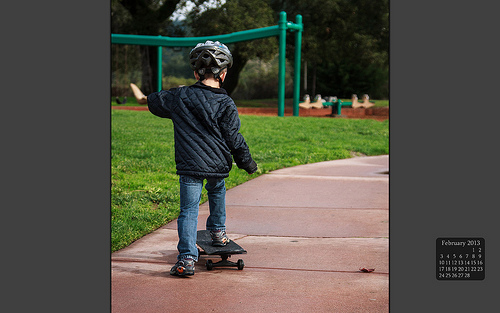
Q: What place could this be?
A: It is a park.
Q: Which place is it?
A: It is a park.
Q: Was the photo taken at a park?
A: Yes, it was taken in a park.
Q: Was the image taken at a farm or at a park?
A: It was taken at a park.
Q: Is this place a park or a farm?
A: It is a park.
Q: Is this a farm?
A: No, it is a park.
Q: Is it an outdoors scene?
A: Yes, it is outdoors.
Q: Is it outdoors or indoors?
A: It is outdoors.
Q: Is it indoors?
A: No, it is outdoors.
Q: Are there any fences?
A: No, there are no fences.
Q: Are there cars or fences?
A: No, there are no fences or cars.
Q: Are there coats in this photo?
A: Yes, there is a coat.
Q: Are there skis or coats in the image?
A: Yes, there is a coat.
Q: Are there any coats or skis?
A: Yes, there is a coat.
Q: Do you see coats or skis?
A: Yes, there is a coat.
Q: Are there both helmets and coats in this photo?
A: Yes, there are both a coat and a helmet.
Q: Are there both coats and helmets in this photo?
A: Yes, there are both a coat and a helmet.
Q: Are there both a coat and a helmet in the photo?
A: Yes, there are both a coat and a helmet.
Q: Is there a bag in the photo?
A: No, there are no bags.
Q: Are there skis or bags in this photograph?
A: No, there are no bags or skis.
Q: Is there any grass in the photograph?
A: Yes, there is grass.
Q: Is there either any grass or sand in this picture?
A: Yes, there is grass.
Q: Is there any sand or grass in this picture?
A: Yes, there is grass.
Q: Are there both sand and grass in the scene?
A: No, there is grass but no sand.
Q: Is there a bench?
A: No, there are no benches.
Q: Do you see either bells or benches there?
A: No, there are no benches or bells.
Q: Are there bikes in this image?
A: No, there are no bikes.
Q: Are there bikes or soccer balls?
A: No, there are no bikes or soccer balls.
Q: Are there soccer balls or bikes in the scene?
A: No, there are no bikes or soccer balls.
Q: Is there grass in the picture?
A: Yes, there is grass.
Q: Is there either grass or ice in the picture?
A: Yes, there is grass.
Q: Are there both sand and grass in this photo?
A: No, there is grass but no sand.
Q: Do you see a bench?
A: No, there are no benches.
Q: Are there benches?
A: No, there are no benches.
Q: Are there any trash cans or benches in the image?
A: No, there are no benches or trash cans.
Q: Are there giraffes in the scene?
A: No, there are no giraffes.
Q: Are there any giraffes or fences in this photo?
A: No, there are no giraffes or fences.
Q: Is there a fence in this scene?
A: No, there are no fences.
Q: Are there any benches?
A: No, there are no benches.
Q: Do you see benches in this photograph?
A: No, there are no benches.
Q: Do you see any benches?
A: No, there are no benches.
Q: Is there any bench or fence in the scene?
A: No, there are no benches or fences.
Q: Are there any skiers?
A: No, there are no skiers.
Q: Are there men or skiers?
A: No, there are no skiers or men.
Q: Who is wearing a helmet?
A: The boy is wearing a helmet.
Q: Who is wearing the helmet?
A: The boy is wearing a helmet.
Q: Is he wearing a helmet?
A: Yes, the boy is wearing a helmet.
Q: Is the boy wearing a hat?
A: No, the boy is wearing a helmet.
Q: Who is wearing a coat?
A: The boy is wearing a coat.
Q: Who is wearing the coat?
A: The boy is wearing a coat.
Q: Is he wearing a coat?
A: Yes, the boy is wearing a coat.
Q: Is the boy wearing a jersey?
A: No, the boy is wearing a coat.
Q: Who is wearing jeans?
A: The boy is wearing jeans.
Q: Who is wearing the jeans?
A: The boy is wearing jeans.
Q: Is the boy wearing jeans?
A: Yes, the boy is wearing jeans.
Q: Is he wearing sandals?
A: No, the boy is wearing jeans.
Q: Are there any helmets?
A: Yes, there is a helmet.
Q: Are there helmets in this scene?
A: Yes, there is a helmet.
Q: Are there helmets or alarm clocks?
A: Yes, there is a helmet.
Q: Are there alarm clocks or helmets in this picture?
A: Yes, there is a helmet.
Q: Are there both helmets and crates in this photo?
A: No, there is a helmet but no crates.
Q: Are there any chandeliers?
A: No, there are no chandeliers.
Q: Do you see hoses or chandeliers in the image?
A: No, there are no chandeliers or hoses.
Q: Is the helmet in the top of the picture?
A: Yes, the helmet is in the top of the image.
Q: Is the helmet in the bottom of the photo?
A: No, the helmet is in the top of the image.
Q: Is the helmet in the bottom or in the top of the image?
A: The helmet is in the top of the image.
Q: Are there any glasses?
A: No, there are no glasses.